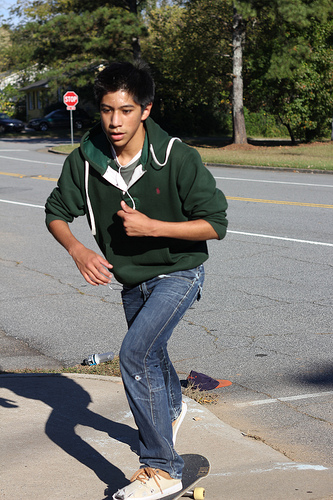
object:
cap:
[186, 369, 233, 389]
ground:
[3, 138, 331, 498]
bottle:
[82, 353, 100, 365]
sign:
[63, 89, 79, 145]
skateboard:
[114, 454, 209, 500]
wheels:
[193, 488, 206, 499]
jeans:
[117, 263, 204, 479]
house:
[0, 61, 69, 123]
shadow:
[1, 369, 140, 499]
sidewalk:
[0, 372, 332, 498]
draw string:
[82, 160, 95, 235]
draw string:
[148, 136, 184, 167]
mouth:
[108, 129, 126, 140]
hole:
[116, 488, 129, 498]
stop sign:
[63, 90, 79, 110]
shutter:
[37, 91, 41, 109]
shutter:
[29, 94, 33, 109]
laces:
[128, 466, 158, 485]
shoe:
[113, 467, 185, 497]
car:
[27, 104, 91, 132]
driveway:
[1, 133, 333, 476]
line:
[234, 387, 331, 410]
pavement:
[0, 137, 333, 500]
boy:
[46, 52, 227, 500]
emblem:
[156, 187, 161, 194]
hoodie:
[42, 113, 228, 288]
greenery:
[186, 31, 213, 69]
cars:
[0, 111, 26, 136]